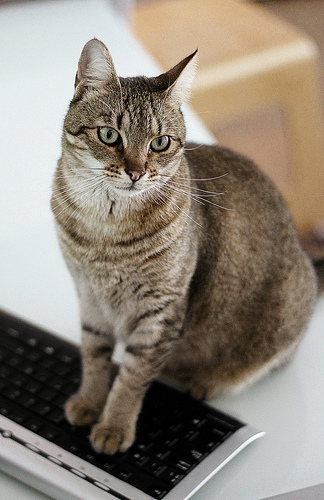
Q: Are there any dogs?
A: No, there are no dogs.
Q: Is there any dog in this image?
A: No, there are no dogs.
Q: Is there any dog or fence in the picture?
A: No, there are no dogs or fences.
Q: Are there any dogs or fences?
A: No, there are no dogs or fences.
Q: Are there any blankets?
A: No, there are no blankets.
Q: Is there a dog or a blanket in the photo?
A: No, there are no blankets or dogs.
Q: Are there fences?
A: No, there are no fences.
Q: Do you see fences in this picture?
A: No, there are no fences.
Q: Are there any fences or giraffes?
A: No, there are no fences or giraffes.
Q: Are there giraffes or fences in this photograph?
A: No, there are no fences or giraffes.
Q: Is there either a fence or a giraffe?
A: No, there are no fences or giraffes.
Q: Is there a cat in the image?
A: Yes, there is a cat.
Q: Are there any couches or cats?
A: Yes, there is a cat.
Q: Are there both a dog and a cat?
A: No, there is a cat but no dogs.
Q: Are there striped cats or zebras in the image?
A: Yes, there is a striped cat.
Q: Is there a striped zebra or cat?
A: Yes, there is a striped cat.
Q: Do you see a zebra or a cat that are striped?
A: Yes, the cat is striped.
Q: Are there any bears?
A: No, there are no bears.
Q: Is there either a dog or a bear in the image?
A: No, there are no bears or dogs.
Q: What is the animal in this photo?
A: The animal is a cat.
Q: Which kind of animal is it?
A: The animal is a cat.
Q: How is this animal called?
A: This is a cat.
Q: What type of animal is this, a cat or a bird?
A: This is a cat.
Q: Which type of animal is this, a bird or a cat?
A: This is a cat.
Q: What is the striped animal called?
A: The animal is a cat.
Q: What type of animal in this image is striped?
A: The animal is a cat.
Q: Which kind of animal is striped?
A: The animal is a cat.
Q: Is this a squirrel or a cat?
A: This is a cat.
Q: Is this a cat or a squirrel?
A: This is a cat.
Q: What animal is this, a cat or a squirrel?
A: This is a cat.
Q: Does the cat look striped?
A: Yes, the cat is striped.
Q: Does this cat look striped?
A: Yes, the cat is striped.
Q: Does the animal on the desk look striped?
A: Yes, the cat is striped.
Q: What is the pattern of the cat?
A: The cat is striped.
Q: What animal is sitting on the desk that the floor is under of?
A: The cat is sitting on the desk.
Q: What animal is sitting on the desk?
A: The cat is sitting on the desk.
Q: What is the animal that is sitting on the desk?
A: The animal is a cat.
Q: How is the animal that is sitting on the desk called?
A: The animal is a cat.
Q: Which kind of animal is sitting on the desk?
A: The animal is a cat.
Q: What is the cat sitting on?
A: The cat is sitting on the desk.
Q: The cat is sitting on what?
A: The cat is sitting on the desk.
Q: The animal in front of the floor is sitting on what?
A: The cat is sitting on the desk.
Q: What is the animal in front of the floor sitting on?
A: The cat is sitting on the desk.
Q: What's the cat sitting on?
A: The cat is sitting on the desk.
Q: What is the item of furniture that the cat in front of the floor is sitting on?
A: The piece of furniture is a desk.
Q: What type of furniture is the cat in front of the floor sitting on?
A: The cat is sitting on the desk.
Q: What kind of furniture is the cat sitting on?
A: The cat is sitting on the desk.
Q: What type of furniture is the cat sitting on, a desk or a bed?
A: The cat is sitting on a desk.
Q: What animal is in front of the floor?
A: The animal is a cat.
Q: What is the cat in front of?
A: The cat is in front of the floor.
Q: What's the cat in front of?
A: The cat is in front of the floor.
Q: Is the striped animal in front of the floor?
A: Yes, the cat is in front of the floor.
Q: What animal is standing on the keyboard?
A: The cat is standing on the keyboard.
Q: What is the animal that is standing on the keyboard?
A: The animal is a cat.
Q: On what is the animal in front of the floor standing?
A: The cat is standing on the keyboard.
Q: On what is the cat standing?
A: The cat is standing on the keyboard.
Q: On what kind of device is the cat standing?
A: The cat is standing on the keyboard.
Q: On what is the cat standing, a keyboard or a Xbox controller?
A: The cat is standing on a keyboard.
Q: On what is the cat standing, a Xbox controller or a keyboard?
A: The cat is standing on a keyboard.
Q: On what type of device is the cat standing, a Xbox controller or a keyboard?
A: The cat is standing on a keyboard.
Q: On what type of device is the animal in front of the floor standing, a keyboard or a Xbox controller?
A: The cat is standing on a keyboard.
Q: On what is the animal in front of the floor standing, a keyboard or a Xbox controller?
A: The cat is standing on a keyboard.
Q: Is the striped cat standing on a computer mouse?
A: No, the cat is standing on the keyboard.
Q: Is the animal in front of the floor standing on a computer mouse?
A: No, the cat is standing on the keyboard.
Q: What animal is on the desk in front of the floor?
A: The animal is a cat.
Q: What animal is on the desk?
A: The animal is a cat.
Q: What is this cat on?
A: The cat is on the desk.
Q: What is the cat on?
A: The cat is on the desk.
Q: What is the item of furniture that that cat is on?
A: The piece of furniture is a desk.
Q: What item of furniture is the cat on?
A: The cat is on the desk.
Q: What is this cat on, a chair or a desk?
A: The cat is on a desk.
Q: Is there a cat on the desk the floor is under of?
A: Yes, there is a cat on the desk.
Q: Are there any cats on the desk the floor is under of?
A: Yes, there is a cat on the desk.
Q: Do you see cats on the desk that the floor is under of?
A: Yes, there is a cat on the desk.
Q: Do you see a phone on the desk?
A: No, there is a cat on the desk.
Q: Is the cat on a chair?
A: No, the cat is on the desk.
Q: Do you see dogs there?
A: No, there are no dogs.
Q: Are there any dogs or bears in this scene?
A: No, there are no dogs or bears.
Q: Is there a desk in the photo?
A: Yes, there is a desk.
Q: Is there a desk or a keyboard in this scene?
A: Yes, there is a desk.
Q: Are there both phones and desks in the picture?
A: No, there is a desk but no phones.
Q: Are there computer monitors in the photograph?
A: No, there are no computer monitors.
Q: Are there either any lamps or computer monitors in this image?
A: No, there are no computer monitors or lamps.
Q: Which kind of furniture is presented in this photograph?
A: The furniture is a desk.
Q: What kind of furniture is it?
A: The piece of furniture is a desk.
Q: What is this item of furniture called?
A: This is a desk.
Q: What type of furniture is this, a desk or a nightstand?
A: This is a desk.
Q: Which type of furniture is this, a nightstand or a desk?
A: This is a desk.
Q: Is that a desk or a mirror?
A: That is a desk.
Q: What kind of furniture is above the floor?
A: The piece of furniture is a desk.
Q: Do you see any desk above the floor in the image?
A: Yes, there is a desk above the floor.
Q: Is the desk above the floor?
A: Yes, the desk is above the floor.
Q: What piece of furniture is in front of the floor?
A: The piece of furniture is a desk.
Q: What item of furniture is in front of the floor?
A: The piece of furniture is a desk.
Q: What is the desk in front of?
A: The desk is in front of the floor.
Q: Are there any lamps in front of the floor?
A: No, there is a desk in front of the floor.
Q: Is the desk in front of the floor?
A: Yes, the desk is in front of the floor.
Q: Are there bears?
A: No, there are no bears.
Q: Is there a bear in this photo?
A: No, there are no bears.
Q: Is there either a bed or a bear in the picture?
A: No, there are no bears or beds.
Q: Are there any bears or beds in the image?
A: No, there are no bears or beds.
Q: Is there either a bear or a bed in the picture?
A: No, there are no bears or beds.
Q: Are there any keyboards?
A: Yes, there is a keyboard.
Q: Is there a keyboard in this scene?
A: Yes, there is a keyboard.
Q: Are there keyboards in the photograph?
A: Yes, there is a keyboard.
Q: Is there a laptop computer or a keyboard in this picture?
A: Yes, there is a keyboard.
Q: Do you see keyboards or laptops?
A: Yes, there is a keyboard.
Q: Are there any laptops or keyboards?
A: Yes, there is a keyboard.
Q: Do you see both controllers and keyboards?
A: No, there is a keyboard but no controllers.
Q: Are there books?
A: No, there are no books.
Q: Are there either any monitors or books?
A: No, there are no books or monitors.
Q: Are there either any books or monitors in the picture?
A: No, there are no books or monitors.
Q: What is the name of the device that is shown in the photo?
A: The device is a keyboard.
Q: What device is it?
A: The device is a keyboard.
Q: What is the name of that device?
A: This is a keyboard.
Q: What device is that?
A: This is a keyboard.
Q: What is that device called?
A: This is a keyboard.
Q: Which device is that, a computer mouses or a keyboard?
A: This is a keyboard.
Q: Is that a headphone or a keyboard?
A: That is a keyboard.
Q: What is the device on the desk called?
A: The device is a keyboard.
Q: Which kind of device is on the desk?
A: The device is a keyboard.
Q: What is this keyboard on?
A: The keyboard is on the desk.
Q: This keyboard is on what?
A: The keyboard is on the desk.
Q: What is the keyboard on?
A: The keyboard is on the desk.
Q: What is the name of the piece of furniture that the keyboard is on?
A: The piece of furniture is a desk.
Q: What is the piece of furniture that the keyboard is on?
A: The piece of furniture is a desk.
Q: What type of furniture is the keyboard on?
A: The keyboard is on the desk.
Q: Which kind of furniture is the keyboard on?
A: The keyboard is on the desk.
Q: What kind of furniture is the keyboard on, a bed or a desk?
A: The keyboard is on a desk.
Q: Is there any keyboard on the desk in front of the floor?
A: Yes, there is a keyboard on the desk.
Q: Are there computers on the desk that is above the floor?
A: No, there is a keyboard on the desk.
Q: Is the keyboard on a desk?
A: Yes, the keyboard is on a desk.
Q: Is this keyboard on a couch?
A: No, the keyboard is on a desk.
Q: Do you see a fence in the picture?
A: No, there are no fences.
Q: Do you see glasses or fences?
A: No, there are no fences or glasses.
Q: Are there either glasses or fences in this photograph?
A: No, there are no fences or glasses.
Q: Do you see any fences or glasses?
A: No, there are no fences or glasses.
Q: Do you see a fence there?
A: No, there are no fences.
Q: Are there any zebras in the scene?
A: No, there are no zebras.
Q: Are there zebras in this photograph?
A: No, there are no zebras.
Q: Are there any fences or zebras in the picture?
A: No, there are no zebras or fences.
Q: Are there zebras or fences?
A: No, there are no zebras or fences.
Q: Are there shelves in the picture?
A: No, there are no shelves.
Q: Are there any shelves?
A: No, there are no shelves.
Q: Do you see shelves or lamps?
A: No, there are no shelves or lamps.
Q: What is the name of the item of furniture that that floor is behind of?
A: The piece of furniture is a desk.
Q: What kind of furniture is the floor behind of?
A: The floor is behind the desk.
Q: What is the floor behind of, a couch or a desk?
A: The floor is behind a desk.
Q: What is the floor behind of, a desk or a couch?
A: The floor is behind a desk.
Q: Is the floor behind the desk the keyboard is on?
A: Yes, the floor is behind the desk.